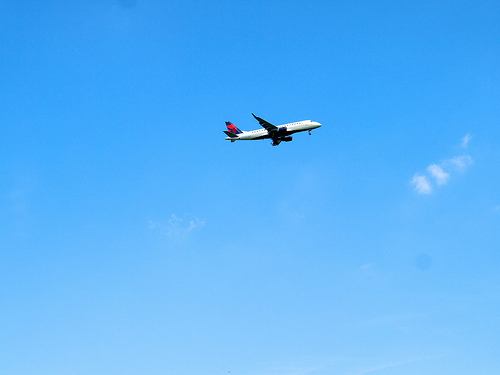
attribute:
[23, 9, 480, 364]
airplane sky — clear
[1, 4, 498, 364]
sky — blue, white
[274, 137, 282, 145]
wheel — down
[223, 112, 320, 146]
airplane — white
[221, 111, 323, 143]
airplane — red, blue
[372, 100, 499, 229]
cloud — White, very wispy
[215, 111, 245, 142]
accents — blue, red